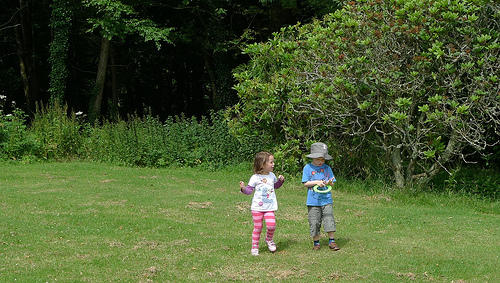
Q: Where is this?
A: This is at the backyard.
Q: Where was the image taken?
A: It was taken at the backyard.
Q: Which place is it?
A: It is a backyard.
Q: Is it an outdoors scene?
A: Yes, it is outdoors.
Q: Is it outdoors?
A: Yes, it is outdoors.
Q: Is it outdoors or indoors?
A: It is outdoors.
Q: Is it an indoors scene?
A: No, it is outdoors.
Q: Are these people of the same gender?
A: No, they are both male and female.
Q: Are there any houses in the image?
A: No, there are no houses.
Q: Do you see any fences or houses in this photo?
A: No, there are no houses or fences.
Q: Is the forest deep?
A: Yes, the forest is deep.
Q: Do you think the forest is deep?
A: Yes, the forest is deep.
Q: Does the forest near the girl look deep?
A: Yes, the forest is deep.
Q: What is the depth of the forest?
A: The forest is deep.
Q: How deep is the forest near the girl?
A: The forest is deep.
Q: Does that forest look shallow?
A: No, the forest is deep.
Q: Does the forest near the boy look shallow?
A: No, the forest is deep.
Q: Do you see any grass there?
A: Yes, there is grass.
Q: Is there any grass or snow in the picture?
A: Yes, there is grass.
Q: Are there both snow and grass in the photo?
A: No, there is grass but no snow.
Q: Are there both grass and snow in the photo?
A: No, there is grass but no snow.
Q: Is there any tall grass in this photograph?
A: Yes, there is tall grass.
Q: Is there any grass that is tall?
A: Yes, there is grass that is tall.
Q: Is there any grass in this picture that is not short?
A: Yes, there is tall grass.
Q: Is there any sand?
A: No, there is no sand.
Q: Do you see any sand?
A: No, there is no sand.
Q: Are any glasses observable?
A: No, there are no glasses.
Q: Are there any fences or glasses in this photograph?
A: No, there are no glasses or fences.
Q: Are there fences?
A: No, there are no fences.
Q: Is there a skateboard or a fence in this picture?
A: No, there are no fences or skateboards.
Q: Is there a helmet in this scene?
A: No, there are no helmets.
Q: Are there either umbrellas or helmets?
A: No, there are no helmets or umbrellas.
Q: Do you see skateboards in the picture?
A: No, there are no skateboards.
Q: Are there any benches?
A: No, there are no benches.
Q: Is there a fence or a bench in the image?
A: No, there are no benches or fences.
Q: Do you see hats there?
A: Yes, there is a hat.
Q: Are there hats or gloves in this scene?
A: Yes, there is a hat.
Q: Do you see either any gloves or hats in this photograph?
A: Yes, there is a hat.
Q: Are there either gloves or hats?
A: Yes, there is a hat.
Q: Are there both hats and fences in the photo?
A: No, there is a hat but no fences.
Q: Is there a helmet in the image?
A: No, there are no helmets.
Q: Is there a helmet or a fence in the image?
A: No, there are no helmets or fences.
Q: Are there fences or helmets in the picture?
A: No, there are no helmets or fences.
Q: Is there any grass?
A: Yes, there is grass.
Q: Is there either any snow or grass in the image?
A: Yes, there is grass.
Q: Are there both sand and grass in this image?
A: No, there is grass but no sand.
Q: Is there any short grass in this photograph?
A: Yes, there is short grass.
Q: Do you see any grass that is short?
A: Yes, there is grass that is short.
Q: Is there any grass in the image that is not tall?
A: Yes, there is short grass.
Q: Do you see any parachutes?
A: No, there are no parachutes.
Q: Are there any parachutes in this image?
A: No, there are no parachutes.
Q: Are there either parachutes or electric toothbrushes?
A: No, there are no parachutes or electric toothbrushes.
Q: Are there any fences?
A: No, there are no fences.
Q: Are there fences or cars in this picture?
A: No, there are no fences or cars.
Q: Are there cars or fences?
A: No, there are no fences or cars.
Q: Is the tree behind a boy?
A: Yes, the tree is behind a boy.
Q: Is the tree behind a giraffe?
A: No, the tree is behind a boy.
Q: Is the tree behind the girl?
A: Yes, the tree is behind the girl.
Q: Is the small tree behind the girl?
A: Yes, the tree is behind the girl.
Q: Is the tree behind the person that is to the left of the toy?
A: Yes, the tree is behind the girl.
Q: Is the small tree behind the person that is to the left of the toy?
A: Yes, the tree is behind the girl.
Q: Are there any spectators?
A: No, there are no spectators.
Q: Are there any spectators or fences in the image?
A: No, there are no spectators or fences.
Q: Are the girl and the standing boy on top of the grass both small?
A: Yes, both the girl and the boy are small.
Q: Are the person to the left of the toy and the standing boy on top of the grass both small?
A: Yes, both the girl and the boy are small.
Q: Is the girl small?
A: Yes, the girl is small.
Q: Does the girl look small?
A: Yes, the girl is small.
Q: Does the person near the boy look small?
A: Yes, the girl is small.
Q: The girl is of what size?
A: The girl is small.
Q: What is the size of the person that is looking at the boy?
A: The girl is small.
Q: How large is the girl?
A: The girl is small.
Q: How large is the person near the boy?
A: The girl is small.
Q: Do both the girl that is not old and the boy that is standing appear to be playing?
A: Yes, both the girl and the boy are playing.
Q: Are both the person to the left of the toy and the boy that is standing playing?
A: Yes, both the girl and the boy are playing.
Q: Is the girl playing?
A: Yes, the girl is playing.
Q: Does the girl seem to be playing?
A: Yes, the girl is playing.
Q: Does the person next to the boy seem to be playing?
A: Yes, the girl is playing.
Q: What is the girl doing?
A: The girl is playing.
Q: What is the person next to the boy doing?
A: The girl is playing.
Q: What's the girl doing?
A: The girl is playing.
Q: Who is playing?
A: The girl is playing.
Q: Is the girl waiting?
A: No, the girl is playing.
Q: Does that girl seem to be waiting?
A: No, the girl is playing.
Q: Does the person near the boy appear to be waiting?
A: No, the girl is playing.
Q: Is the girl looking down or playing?
A: The girl is playing.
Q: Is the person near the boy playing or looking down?
A: The girl is playing.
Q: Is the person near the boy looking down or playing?
A: The girl is playing.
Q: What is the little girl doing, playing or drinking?
A: The girl is playing.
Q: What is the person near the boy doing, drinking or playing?
A: The girl is playing.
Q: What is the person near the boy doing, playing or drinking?
A: The girl is playing.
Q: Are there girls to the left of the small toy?
A: Yes, there is a girl to the left of the toy.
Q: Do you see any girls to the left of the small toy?
A: Yes, there is a girl to the left of the toy.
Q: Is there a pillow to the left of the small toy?
A: No, there is a girl to the left of the toy.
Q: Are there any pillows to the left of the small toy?
A: No, there is a girl to the left of the toy.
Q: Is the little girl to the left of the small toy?
A: Yes, the girl is to the left of the toy.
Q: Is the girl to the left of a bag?
A: No, the girl is to the left of the toy.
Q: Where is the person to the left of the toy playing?
A: The girl is playing on the grass.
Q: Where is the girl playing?
A: The girl is playing on the grass.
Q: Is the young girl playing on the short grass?
A: Yes, the girl is playing on the grass.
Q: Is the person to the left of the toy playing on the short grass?
A: Yes, the girl is playing on the grass.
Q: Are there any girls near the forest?
A: Yes, there is a girl near the forest.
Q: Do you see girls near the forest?
A: Yes, there is a girl near the forest.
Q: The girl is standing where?
A: The girl is standing in the backyard.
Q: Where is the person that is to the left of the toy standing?
A: The girl is standing in the backyard.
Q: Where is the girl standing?
A: The girl is standing in the backyard.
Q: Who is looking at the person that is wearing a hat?
A: The girl is looking at the boy.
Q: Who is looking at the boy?
A: The girl is looking at the boy.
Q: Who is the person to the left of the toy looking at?
A: The girl is looking at the boy.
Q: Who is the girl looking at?
A: The girl is looking at the boy.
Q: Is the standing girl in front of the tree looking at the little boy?
A: Yes, the girl is looking at the boy.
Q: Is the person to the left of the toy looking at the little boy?
A: Yes, the girl is looking at the boy.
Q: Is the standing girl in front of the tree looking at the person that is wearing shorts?
A: Yes, the girl is looking at the boy.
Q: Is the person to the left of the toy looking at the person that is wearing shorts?
A: Yes, the girl is looking at the boy.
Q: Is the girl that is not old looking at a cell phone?
A: No, the girl is looking at the boy.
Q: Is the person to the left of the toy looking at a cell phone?
A: No, the girl is looking at the boy.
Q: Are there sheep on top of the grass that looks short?
A: No, there is a girl on top of the grass.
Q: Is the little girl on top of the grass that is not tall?
A: Yes, the girl is on top of the grass.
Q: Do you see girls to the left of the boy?
A: Yes, there is a girl to the left of the boy.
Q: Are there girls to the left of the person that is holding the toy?
A: Yes, there is a girl to the left of the boy.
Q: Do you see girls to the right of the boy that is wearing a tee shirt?
A: No, the girl is to the left of the boy.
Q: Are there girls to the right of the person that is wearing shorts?
A: No, the girl is to the left of the boy.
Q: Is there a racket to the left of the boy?
A: No, there is a girl to the left of the boy.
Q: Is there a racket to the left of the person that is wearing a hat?
A: No, there is a girl to the left of the boy.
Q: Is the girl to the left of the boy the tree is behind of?
A: Yes, the girl is to the left of the boy.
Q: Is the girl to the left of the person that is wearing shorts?
A: Yes, the girl is to the left of the boy.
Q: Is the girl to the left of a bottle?
A: No, the girl is to the left of the boy.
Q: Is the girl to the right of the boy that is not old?
A: No, the girl is to the left of the boy.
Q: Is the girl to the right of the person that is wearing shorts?
A: No, the girl is to the left of the boy.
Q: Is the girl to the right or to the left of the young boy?
A: The girl is to the left of the boy.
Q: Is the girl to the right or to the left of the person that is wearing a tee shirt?
A: The girl is to the left of the boy.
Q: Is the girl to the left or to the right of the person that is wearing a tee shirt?
A: The girl is to the left of the boy.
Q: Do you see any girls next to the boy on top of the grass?
A: Yes, there is a girl next to the boy.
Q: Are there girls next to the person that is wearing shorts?
A: Yes, there is a girl next to the boy.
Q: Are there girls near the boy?
A: Yes, there is a girl near the boy.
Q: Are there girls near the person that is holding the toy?
A: Yes, there is a girl near the boy.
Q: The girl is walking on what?
A: The girl is walking on the grass.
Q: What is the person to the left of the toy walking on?
A: The girl is walking on the grass.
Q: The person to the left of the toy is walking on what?
A: The girl is walking on the grass.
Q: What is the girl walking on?
A: The girl is walking on the grass.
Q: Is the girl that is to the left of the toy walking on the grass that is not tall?
A: Yes, the girl is walking on the grass.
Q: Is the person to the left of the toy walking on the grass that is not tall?
A: Yes, the girl is walking on the grass.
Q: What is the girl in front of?
A: The girl is in front of the tree.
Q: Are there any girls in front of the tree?
A: Yes, there is a girl in front of the tree.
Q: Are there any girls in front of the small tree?
A: Yes, there is a girl in front of the tree.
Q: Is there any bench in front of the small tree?
A: No, there is a girl in front of the tree.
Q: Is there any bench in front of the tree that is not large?
A: No, there is a girl in front of the tree.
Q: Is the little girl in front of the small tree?
A: Yes, the girl is in front of the tree.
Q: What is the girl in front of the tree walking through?
A: The girl is walking through the grass.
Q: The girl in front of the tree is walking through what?
A: The girl is walking through the grass.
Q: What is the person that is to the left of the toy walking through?
A: The girl is walking through the grass.